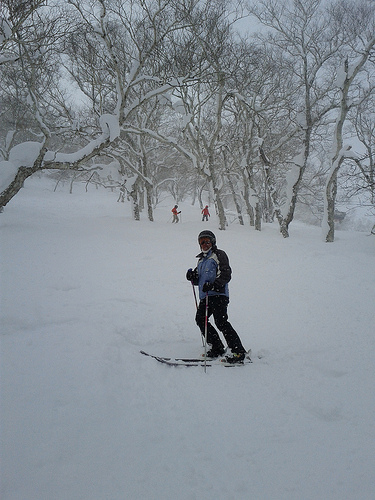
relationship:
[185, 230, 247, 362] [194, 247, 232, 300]
man has jacket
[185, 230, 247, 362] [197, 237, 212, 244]
man wearing goggles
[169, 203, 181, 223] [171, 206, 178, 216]
person wearing jacket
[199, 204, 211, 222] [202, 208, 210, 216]
person wearing jacket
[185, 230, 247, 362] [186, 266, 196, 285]
man wearing glove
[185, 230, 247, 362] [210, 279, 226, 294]
man wearing glove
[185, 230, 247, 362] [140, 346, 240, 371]
man riding skis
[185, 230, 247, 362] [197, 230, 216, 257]
man has head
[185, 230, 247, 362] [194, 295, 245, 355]
man wearing pants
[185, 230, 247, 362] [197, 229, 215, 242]
man wearing helmet